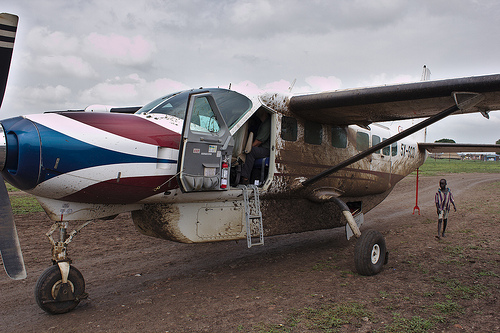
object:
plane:
[0, 12, 500, 316]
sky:
[0, 0, 499, 135]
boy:
[433, 178, 456, 238]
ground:
[0, 178, 500, 333]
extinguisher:
[220, 161, 230, 190]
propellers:
[0, 167, 28, 281]